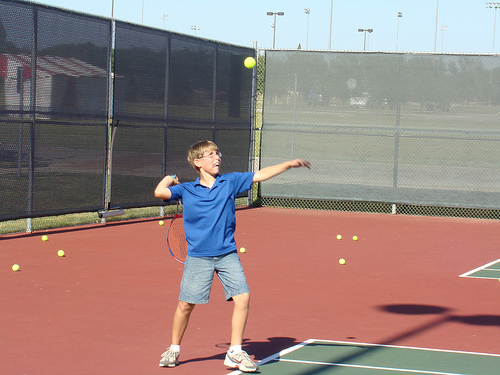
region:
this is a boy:
[41, 13, 453, 325]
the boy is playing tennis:
[35, 51, 488, 371]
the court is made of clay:
[291, 238, 468, 365]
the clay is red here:
[292, 264, 420, 321]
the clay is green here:
[303, 339, 435, 374]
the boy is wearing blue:
[147, 138, 355, 315]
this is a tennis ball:
[222, 43, 290, 83]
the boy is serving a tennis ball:
[114, 53, 360, 295]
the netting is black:
[18, 2, 499, 298]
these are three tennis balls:
[16, 225, 83, 293]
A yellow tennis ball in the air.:
[241, 51, 256, 69]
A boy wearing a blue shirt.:
[153, 138, 313, 373]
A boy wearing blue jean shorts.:
[153, 138, 311, 372]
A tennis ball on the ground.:
[338, 254, 350, 266]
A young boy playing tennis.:
[152, 135, 313, 371]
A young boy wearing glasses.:
[151, 136, 313, 371]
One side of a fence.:
[0, 0, 254, 218]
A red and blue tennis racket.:
[163, 175, 188, 265]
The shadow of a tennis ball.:
[345, 330, 359, 341]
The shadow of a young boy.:
[165, 335, 379, 370]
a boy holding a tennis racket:
[130, 135, 309, 368]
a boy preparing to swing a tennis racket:
[146, 142, 283, 372]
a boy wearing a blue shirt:
[147, 147, 293, 373]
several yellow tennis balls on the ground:
[13, 213, 373, 273]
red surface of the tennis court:
[34, 285, 132, 365]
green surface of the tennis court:
[307, 347, 376, 372]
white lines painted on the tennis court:
[280, 321, 358, 373]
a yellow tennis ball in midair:
[239, 55, 264, 70]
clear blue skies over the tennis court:
[197, 1, 262, 31]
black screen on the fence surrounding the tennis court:
[319, 66, 438, 195]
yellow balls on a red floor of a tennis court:
[13, 233, 358, 274]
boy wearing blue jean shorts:
[178, 253, 248, 303]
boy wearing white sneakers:
[157, 343, 259, 373]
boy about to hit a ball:
[156, 138, 310, 373]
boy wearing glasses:
[193, 148, 222, 159]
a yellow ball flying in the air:
[244, 55, 255, 67]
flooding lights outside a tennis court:
[266, 10, 374, 50]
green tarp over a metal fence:
[1, 1, 498, 221]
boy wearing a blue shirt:
[168, 170, 254, 252]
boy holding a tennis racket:
[156, 172, 187, 266]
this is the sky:
[212, 4, 232, 16]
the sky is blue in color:
[200, 3, 240, 24]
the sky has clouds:
[216, 22, 253, 33]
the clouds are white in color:
[333, 33, 344, 44]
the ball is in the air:
[238, 54, 263, 75]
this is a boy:
[151, 136, 285, 363]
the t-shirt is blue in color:
[185, 196, 208, 216]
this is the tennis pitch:
[54, 295, 150, 341]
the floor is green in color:
[310, 346, 337, 356]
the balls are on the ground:
[6, 214, 361, 274]